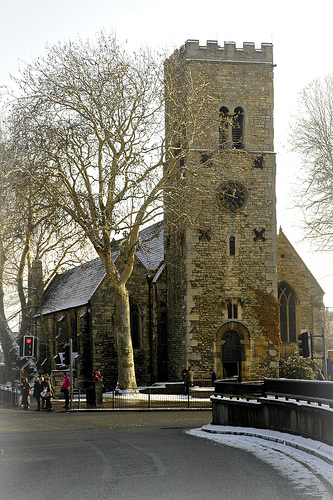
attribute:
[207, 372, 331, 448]
fence — small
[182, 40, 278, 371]
wall — church wall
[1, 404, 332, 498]
intersection — large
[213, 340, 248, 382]
doorway — arch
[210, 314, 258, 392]
entrance — church entrance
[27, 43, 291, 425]
church — old large church, made of stone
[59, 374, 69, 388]
coat — pink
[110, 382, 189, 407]
fence — black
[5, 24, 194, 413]
tree — large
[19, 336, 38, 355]
stop light — a street stop light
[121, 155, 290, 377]
building — large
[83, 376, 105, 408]
trash container — black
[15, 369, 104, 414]
people — standing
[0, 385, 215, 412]
fence — black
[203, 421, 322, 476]
snow — on the ground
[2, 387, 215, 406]
fence — black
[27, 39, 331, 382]
church — infront of the church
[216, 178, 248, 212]
clock — large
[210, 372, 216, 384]
coat — black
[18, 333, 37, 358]
traffic signal — red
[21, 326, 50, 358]
light — traffic light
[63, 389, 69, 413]
pants — black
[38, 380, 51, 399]
bag — white